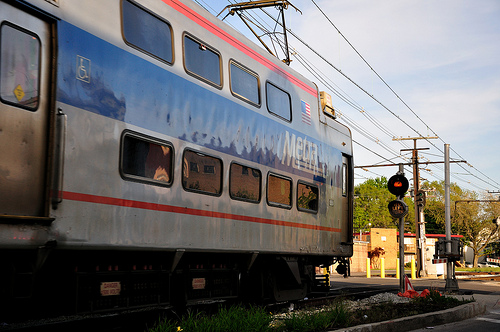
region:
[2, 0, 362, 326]
blue, silver, red and blue train on train tracks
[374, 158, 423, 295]
train traffic light on pole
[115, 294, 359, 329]
patch of grass next to train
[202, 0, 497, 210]
black power lines in sky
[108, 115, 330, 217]
five windows on side of train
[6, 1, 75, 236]
silver door on side of train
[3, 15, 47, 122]
black framed window on train door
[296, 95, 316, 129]
american flag on side of train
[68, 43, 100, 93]
white handicapped sign on side of train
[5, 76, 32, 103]
yellow and black diamond shaped sticker on window of train door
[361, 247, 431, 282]
Yellow posts on the corner.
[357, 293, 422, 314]
Rocks on the side of tracks.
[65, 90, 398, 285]
Train on the tracks.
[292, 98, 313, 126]
A flag on the train.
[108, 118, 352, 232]
Windows on the train.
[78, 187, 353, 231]
Red line on the side of train.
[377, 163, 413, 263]
Railroad light on pole.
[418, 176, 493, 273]
Trees by the building.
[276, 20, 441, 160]
Wires connected to the poles.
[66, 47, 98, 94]
Handicap sign on the train.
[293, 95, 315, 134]
American flag painted on side of train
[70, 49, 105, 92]
blue and white handicap logo painted on train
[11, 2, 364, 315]
silver train with red and blue paint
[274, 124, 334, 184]
company logo painted on side of train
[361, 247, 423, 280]
four concrete posts painted yellow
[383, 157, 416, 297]
signal light for train illuminated in red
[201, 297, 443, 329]
grass growing out of center island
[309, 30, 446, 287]
post holding up power lines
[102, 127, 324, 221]
passenger windows in a line on train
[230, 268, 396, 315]
train traveling on train tracks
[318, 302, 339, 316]
part of a grass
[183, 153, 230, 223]
part of a window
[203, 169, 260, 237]
side of a train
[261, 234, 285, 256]
edge of a train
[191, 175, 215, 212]
part of a train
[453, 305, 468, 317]
edge of a road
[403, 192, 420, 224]
part of a post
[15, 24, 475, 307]
This picture is taken at a station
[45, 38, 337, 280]
This is a train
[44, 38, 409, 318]
This train is passenger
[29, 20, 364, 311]
The train is silver, red, and blue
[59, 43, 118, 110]
This is handicap sign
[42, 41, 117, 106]
The sign is blue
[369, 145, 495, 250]
This is a traffic signal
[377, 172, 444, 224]
The signal is red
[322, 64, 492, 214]
These are power lines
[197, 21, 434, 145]
The train runs on electric